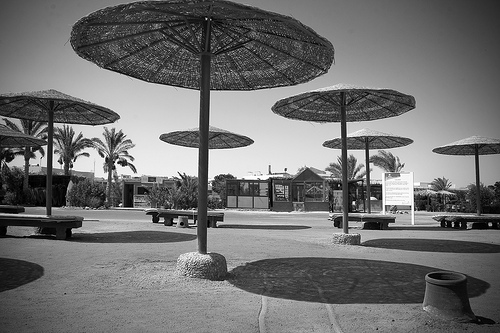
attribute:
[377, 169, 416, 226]
sign — white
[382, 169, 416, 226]
sign — White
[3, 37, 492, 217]
umbrellas — large group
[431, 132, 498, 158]
umbrella — tall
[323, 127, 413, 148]
umbrella — tall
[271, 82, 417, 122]
umbrella — tall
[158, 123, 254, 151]
umbrella — tall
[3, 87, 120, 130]
umbrella — tall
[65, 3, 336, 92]
umbrella — tall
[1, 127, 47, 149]
umbrella — tall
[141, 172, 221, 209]
bush — leafy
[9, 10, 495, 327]
picture — black, white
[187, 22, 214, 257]
pole — brown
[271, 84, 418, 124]
umbrella — open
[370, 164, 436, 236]
sign — white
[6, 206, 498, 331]
ground — concrete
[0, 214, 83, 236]
bench — concrete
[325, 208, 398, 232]
bench — stone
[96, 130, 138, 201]
tree — in backgroung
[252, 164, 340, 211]
building — in backgroung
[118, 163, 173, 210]
building — in backgroung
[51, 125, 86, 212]
tree — in backgroung